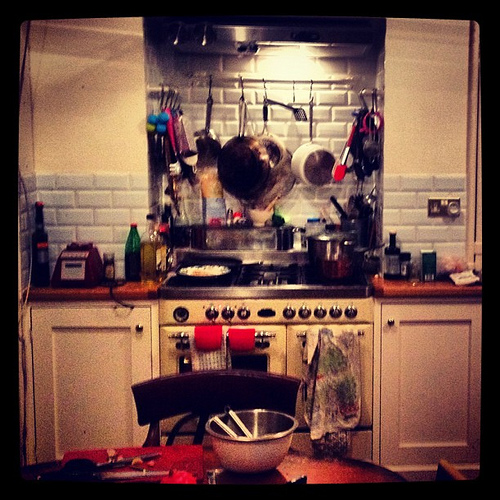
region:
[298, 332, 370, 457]
towel hanging on the stove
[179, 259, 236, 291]
food cooking on the stove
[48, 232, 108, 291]
bottom of electrical appliance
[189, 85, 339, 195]
pots and pans hanging over stove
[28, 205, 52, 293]
tall bottle in the corner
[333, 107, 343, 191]
red spatula hanging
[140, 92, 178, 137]
blue and green items hanging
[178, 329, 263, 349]
two red towels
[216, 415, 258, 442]
spoons in the bowl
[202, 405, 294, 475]
silver mixing bowl with silverware in it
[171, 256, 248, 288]
food on pan on top of stove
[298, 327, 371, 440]
kitchen towel hanging from handle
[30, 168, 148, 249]
rectangle white tiles on wall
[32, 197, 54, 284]
tall neck dark bottle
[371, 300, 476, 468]
white closet door with silver handle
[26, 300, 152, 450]
white closet door with silver handle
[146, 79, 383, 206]
multitude of kitchen artifacts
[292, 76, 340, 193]
white saucepan hanging on hook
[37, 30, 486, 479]
this is a kitchen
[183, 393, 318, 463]
this is a bowl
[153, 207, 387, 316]
this is a stove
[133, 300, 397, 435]
this is a oven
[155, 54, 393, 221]
pots hanging on wall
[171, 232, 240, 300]
skillet on the stove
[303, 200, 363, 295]
pot on the stove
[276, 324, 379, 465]
towel hanging on over door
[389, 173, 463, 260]
white subway tile on wall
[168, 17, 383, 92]
a silver vent hood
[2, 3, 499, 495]
this is a kitchen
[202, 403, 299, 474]
this is a bowl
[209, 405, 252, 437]
these are silver utensils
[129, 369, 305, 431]
this is a chair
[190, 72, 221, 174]
that's a pot hanging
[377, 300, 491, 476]
this is a cabinet door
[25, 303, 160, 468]
this is another cabinet door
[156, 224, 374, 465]
this is a stove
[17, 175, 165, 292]
this is tile on wall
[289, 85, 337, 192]
this is a white pan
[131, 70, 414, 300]
These are kitchen appliances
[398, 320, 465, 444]
White paint on door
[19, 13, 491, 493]
The image has bad lighting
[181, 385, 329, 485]
A bowl on the table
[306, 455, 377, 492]
This is made of wood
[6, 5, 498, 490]
A black frame on the picture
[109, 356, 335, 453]
Wooden chair in the shot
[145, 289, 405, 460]
Towers on the stove's door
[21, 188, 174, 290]
Bottles on the counter